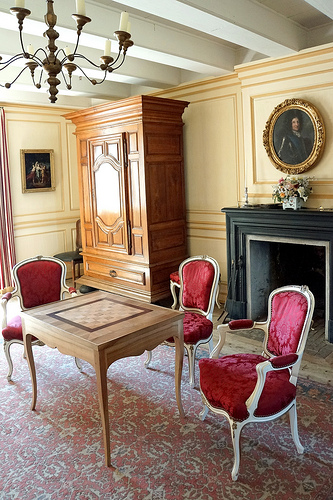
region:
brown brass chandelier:
[0, 1, 134, 103]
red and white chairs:
[0, 254, 315, 482]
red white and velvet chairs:
[0, 255, 303, 484]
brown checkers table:
[19, 288, 188, 469]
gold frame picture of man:
[262, 97, 325, 174]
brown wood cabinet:
[60, 94, 186, 304]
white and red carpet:
[0, 334, 332, 499]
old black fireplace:
[220, 204, 331, 340]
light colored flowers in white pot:
[271, 174, 312, 209]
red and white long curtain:
[0, 107, 14, 287]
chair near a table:
[209, 277, 308, 489]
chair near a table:
[176, 244, 221, 301]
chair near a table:
[27, 253, 67, 291]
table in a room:
[84, 324, 142, 464]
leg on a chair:
[214, 426, 249, 488]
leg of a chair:
[280, 396, 303, 456]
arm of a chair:
[250, 361, 290, 406]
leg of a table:
[92, 363, 120, 467]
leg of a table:
[168, 333, 191, 424]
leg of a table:
[23, 340, 49, 409]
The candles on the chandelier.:
[0, 4, 127, 103]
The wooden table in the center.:
[13, 286, 186, 456]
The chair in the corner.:
[44, 218, 80, 270]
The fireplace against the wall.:
[219, 197, 326, 318]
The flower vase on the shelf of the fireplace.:
[279, 196, 302, 209]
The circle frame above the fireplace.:
[252, 100, 318, 161]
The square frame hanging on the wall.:
[14, 146, 50, 182]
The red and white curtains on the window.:
[0, 101, 11, 281]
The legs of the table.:
[16, 333, 186, 459]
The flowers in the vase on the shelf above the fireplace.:
[273, 170, 309, 198]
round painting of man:
[258, 97, 327, 175]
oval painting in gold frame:
[260, 97, 327, 175]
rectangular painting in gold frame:
[17, 146, 57, 195]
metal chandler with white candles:
[0, 0, 135, 105]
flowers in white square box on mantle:
[274, 174, 313, 212]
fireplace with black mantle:
[220, 203, 331, 346]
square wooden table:
[18, 286, 193, 469]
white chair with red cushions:
[200, 280, 316, 484]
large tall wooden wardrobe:
[61, 93, 188, 305]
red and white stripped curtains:
[0, 104, 19, 289]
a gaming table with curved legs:
[21, 289, 187, 469]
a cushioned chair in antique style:
[196, 283, 313, 479]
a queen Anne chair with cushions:
[198, 282, 314, 479]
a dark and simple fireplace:
[221, 206, 332, 340]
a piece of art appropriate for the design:
[19, 148, 56, 195]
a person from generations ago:
[262, 96, 324, 175]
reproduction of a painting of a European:
[262, 99, 322, 174]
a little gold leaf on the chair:
[230, 420, 237, 441]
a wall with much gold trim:
[6, 112, 85, 286]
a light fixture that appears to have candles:
[0, 0, 133, 102]